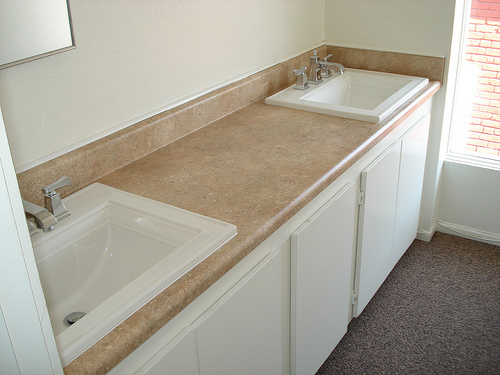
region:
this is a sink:
[20, 168, 228, 356]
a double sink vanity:
[26, 3, 476, 373]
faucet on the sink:
[285, 34, 350, 80]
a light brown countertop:
[125, 53, 355, 228]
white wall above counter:
[22, 0, 342, 110]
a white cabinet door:
[268, 202, 380, 357]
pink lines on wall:
[478, 33, 496, 51]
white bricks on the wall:
[471, 45, 492, 57]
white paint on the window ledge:
[438, 143, 485, 173]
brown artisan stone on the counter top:
[201, 154, 316, 189]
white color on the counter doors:
[263, 270, 362, 329]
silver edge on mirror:
[46, 47, 86, 58]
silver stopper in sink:
[57, 294, 94, 326]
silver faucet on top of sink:
[34, 176, 94, 241]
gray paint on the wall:
[34, 75, 123, 105]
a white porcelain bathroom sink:
[265, 64, 429, 121]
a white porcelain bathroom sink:
[24, 182, 237, 367]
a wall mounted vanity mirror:
[0, 0, 77, 69]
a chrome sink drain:
[62, 311, 84, 326]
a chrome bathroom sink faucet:
[21, 197, 56, 234]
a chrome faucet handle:
[42, 175, 72, 217]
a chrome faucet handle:
[291, 67, 308, 89]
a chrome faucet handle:
[321, 52, 332, 77]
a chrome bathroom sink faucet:
[305, 49, 345, 82]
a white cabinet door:
[291, 182, 356, 374]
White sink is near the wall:
[261, 43, 436, 133]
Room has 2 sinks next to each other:
[3, 5, 476, 374]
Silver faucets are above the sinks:
[291, 36, 350, 91]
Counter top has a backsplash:
[30, 37, 452, 201]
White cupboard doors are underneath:
[267, 156, 389, 363]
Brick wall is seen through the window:
[469, 19, 496, 159]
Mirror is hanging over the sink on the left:
[7, 5, 105, 88]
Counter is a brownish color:
[110, 118, 387, 213]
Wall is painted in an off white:
[26, 12, 408, 165]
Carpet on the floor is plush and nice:
[296, 198, 499, 370]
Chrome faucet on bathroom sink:
[18, 175, 77, 232]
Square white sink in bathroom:
[16, 180, 238, 369]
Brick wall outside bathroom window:
[443, 1, 499, 166]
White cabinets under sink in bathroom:
[48, 87, 438, 374]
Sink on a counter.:
[260, 47, 436, 123]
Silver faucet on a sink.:
[287, 45, 352, 87]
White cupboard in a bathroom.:
[337, 103, 442, 322]